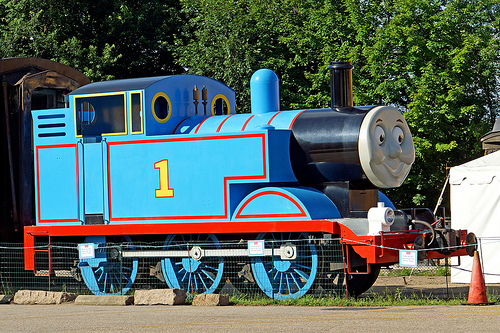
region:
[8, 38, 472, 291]
a large Thomas the Train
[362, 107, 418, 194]
the face on the front of a train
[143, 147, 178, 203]
the number 1 on the side of the train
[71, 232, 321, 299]
the wheels on the side of the train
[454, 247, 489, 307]
an orange safety cone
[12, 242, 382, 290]
a metal fence beside the train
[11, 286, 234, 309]
four flat rocks along the fence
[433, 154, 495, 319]
a white building behind the train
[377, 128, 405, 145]
the black pupils of the train's eyes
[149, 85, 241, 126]
two round windows in the front of the train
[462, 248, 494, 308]
orange cone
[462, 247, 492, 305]
cone in front of train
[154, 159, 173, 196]
The number 1 on the side of the train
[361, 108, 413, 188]
face on the front of train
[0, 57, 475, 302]
blue, red and black train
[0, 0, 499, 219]
trees in the distance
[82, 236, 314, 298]
blue wheels on train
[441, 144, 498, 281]
white tent behind cone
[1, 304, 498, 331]
brown road before fence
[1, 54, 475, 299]
a parked train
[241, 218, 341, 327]
Blue wheel on a train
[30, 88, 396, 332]
Thomas the train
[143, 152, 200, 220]
number one on a train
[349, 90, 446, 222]
Face on a train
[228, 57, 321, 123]
Tube on a train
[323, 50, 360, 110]
Smoke stack on a train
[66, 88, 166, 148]
Window on a train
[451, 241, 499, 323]
Cone on a road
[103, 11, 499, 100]
Green leaves on trees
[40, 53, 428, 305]
Red and blue train engine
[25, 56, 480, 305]
blue and red train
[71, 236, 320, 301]
blue wheels below the train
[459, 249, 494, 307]
the orange safety cone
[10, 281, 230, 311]
rocks along the street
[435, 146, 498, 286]
white tent behind the train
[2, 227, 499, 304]
long metal fence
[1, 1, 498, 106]
green trees in the background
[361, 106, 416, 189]
face on the front of the train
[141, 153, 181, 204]
number one on the side of the train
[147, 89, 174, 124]
circle window on the blue train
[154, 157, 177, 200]
a large red and yellow umber 1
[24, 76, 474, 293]
a blue yellow and red "Thomas the train" train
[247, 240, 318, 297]
a blue train wheel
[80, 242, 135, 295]
a blue train wheel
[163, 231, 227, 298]
a blue train wheel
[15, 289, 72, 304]
a long flat grey stone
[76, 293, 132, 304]
a long flat grey stone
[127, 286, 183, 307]
a long flat grey stone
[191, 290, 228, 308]
a long flat grey stone